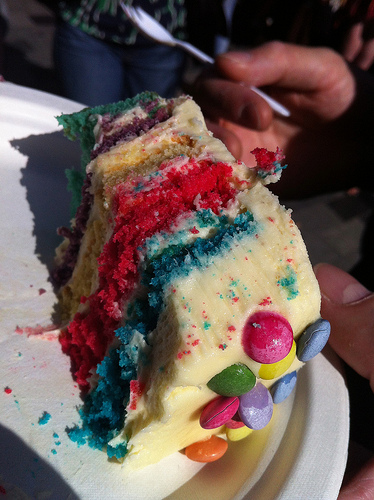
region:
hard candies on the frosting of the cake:
[181, 309, 335, 462]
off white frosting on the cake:
[128, 215, 320, 465]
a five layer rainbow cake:
[49, 87, 250, 457]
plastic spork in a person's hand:
[116, 1, 293, 122]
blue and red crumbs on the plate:
[1, 314, 87, 455]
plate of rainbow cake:
[1, 79, 346, 498]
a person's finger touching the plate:
[312, 255, 372, 359]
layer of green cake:
[65, 88, 165, 208]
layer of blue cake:
[72, 205, 256, 457]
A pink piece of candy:
[238, 305, 285, 354]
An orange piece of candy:
[181, 430, 220, 459]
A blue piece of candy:
[294, 310, 321, 354]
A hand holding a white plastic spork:
[112, 0, 361, 191]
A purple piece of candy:
[236, 375, 267, 420]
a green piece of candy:
[208, 360, 255, 390]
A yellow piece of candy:
[220, 418, 257, 436]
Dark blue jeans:
[51, 14, 191, 110]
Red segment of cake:
[103, 165, 244, 214]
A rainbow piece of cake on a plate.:
[42, 69, 293, 390]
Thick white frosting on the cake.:
[167, 220, 305, 352]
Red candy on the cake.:
[238, 292, 293, 363]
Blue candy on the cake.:
[296, 318, 333, 363]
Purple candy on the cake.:
[236, 375, 279, 430]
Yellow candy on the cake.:
[258, 341, 300, 384]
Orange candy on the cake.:
[187, 429, 231, 468]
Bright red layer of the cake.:
[110, 155, 223, 237]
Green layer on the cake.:
[52, 86, 153, 137]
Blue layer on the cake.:
[154, 208, 256, 279]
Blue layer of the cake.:
[79, 212, 253, 458]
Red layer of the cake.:
[65, 162, 238, 378]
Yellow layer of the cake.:
[60, 139, 191, 321]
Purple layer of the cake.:
[56, 110, 167, 280]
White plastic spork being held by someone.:
[119, 2, 291, 115]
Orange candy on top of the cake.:
[185, 434, 226, 461]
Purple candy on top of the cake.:
[239, 381, 273, 429]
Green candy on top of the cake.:
[209, 361, 256, 394]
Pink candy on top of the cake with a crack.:
[200, 395, 240, 427]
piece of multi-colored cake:
[34, 85, 336, 473]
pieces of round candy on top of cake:
[174, 299, 333, 469]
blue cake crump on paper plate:
[22, 398, 60, 431]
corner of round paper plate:
[167, 361, 368, 497]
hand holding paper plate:
[170, 256, 371, 493]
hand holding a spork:
[115, 2, 300, 127]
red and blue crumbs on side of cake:
[216, 266, 278, 309]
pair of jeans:
[48, 17, 189, 114]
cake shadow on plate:
[4, 121, 95, 298]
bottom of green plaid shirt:
[52, 0, 194, 53]